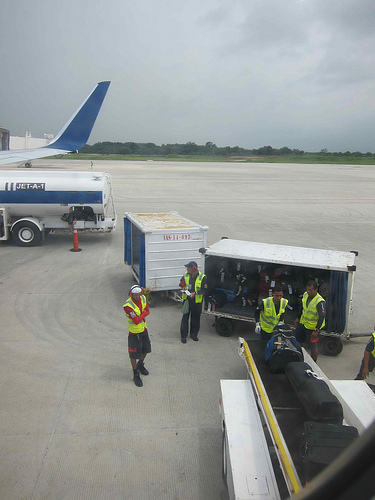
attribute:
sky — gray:
[1, 0, 371, 149]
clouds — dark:
[7, 7, 374, 134]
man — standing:
[124, 297, 150, 335]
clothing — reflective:
[123, 298, 149, 334]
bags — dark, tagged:
[265, 336, 358, 461]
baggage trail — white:
[118, 207, 360, 347]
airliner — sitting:
[3, 79, 116, 164]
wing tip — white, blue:
[34, 81, 117, 144]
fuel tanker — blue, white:
[2, 167, 117, 243]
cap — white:
[132, 284, 141, 294]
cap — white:
[127, 286, 147, 295]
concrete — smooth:
[12, 243, 135, 499]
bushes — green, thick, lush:
[95, 141, 373, 164]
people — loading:
[116, 250, 331, 353]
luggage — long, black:
[282, 358, 344, 417]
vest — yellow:
[255, 298, 292, 329]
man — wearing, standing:
[256, 284, 295, 339]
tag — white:
[300, 362, 325, 380]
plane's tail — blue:
[61, 75, 114, 157]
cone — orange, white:
[69, 218, 85, 258]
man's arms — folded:
[129, 306, 157, 319]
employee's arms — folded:
[124, 302, 151, 326]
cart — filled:
[193, 257, 345, 337]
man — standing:
[176, 253, 213, 342]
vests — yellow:
[167, 275, 356, 329]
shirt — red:
[124, 299, 169, 327]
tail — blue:
[42, 72, 127, 160]